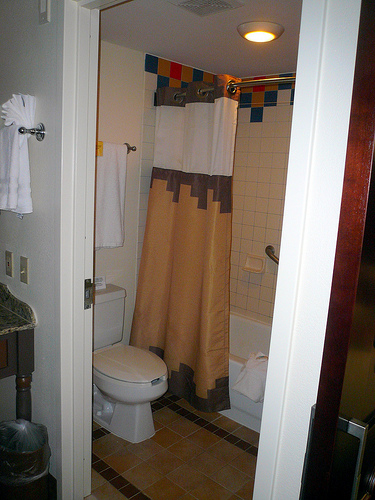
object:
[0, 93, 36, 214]
white towel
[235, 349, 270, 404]
wash rag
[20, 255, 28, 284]
light switch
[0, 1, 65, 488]
wall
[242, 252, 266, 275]
soap dish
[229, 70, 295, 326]
wall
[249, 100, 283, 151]
ground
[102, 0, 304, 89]
ceiling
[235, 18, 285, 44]
bathroom light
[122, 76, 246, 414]
curtain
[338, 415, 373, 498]
door knob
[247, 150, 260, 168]
yellow tiled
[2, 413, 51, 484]
can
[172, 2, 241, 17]
vent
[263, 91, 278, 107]
tile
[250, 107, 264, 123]
tile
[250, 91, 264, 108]
tile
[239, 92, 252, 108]
tile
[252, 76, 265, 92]
tile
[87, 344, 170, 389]
lid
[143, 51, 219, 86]
tile border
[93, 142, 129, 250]
towel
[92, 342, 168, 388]
toilet seat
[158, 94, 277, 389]
shower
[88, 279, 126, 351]
water closet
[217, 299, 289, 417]
bath tub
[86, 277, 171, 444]
toilet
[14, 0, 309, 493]
bathroom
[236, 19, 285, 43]
light fixture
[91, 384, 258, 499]
floor